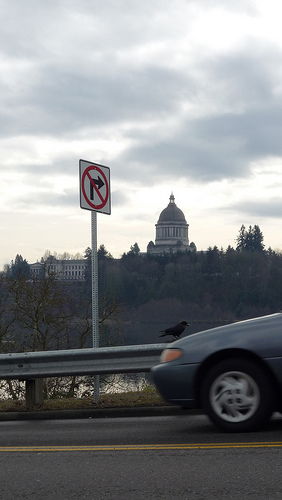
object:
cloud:
[220, 181, 281, 226]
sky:
[6, 4, 281, 260]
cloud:
[17, 144, 74, 212]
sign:
[78, 160, 111, 217]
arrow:
[94, 176, 105, 189]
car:
[151, 313, 281, 436]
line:
[6, 443, 281, 448]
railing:
[0, 344, 161, 408]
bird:
[158, 321, 190, 340]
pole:
[91, 206, 99, 402]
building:
[147, 191, 196, 252]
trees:
[102, 276, 150, 300]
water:
[44, 372, 150, 393]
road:
[7, 421, 277, 496]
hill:
[0, 255, 281, 359]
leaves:
[207, 253, 230, 277]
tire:
[197, 356, 275, 433]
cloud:
[210, 54, 266, 112]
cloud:
[8, 6, 194, 53]